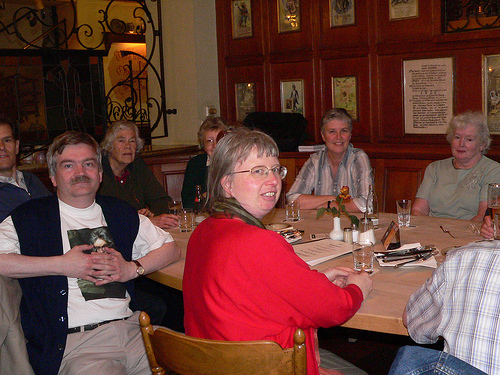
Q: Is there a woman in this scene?
A: Yes, there is a woman.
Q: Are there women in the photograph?
A: Yes, there is a woman.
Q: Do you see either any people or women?
A: Yes, there is a woman.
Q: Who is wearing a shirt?
A: The woman is wearing a shirt.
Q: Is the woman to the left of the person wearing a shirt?
A: Yes, the woman is wearing a shirt.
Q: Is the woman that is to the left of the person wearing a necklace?
A: No, the woman is wearing a shirt.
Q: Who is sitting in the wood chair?
A: The woman is sitting in the chair.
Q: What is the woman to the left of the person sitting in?
A: The woman is sitting in the chair.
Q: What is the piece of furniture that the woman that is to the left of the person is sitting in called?
A: The piece of furniture is a chair.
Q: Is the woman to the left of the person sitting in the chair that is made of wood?
A: Yes, the woman is sitting in the chair.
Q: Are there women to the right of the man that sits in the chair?
A: Yes, there is a woman to the right of the man.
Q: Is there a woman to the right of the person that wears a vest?
A: Yes, there is a woman to the right of the man.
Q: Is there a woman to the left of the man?
A: No, the woman is to the right of the man.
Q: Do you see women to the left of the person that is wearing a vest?
A: No, the woman is to the right of the man.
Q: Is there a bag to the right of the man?
A: No, there is a woman to the right of the man.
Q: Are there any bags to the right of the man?
A: No, there is a woman to the right of the man.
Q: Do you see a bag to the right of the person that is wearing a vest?
A: No, there is a woman to the right of the man.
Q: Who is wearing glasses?
A: The woman is wearing glasses.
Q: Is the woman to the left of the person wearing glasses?
A: Yes, the woman is wearing glasses.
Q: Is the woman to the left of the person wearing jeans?
A: No, the woman is wearing glasses.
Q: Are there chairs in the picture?
A: Yes, there is a chair.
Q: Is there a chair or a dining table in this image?
A: Yes, there is a chair.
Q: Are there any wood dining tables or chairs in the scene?
A: Yes, there is a wood chair.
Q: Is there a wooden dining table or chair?
A: Yes, there is a wood chair.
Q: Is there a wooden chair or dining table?
A: Yes, there is a wood chair.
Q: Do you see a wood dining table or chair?
A: Yes, there is a wood chair.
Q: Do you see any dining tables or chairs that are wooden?
A: Yes, the chair is wooden.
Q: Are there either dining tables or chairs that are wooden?
A: Yes, the chair is wooden.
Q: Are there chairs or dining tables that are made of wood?
A: Yes, the chair is made of wood.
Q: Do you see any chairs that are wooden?
A: Yes, there is a wood chair.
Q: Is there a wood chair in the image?
A: Yes, there is a wood chair.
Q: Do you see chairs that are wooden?
A: Yes, there is a chair that is wooden.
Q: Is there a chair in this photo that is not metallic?
A: Yes, there is a wooden chair.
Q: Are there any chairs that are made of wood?
A: Yes, there is a chair that is made of wood.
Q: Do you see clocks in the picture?
A: No, there are no clocks.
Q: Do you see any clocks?
A: No, there are no clocks.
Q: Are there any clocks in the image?
A: No, there are no clocks.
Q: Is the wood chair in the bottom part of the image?
A: Yes, the chair is in the bottom of the image.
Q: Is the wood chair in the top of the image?
A: No, the chair is in the bottom of the image.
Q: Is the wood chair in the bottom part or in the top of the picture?
A: The chair is in the bottom of the image.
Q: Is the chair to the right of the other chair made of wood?
A: Yes, the chair is made of wood.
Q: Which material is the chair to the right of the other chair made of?
A: The chair is made of wood.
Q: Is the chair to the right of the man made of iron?
A: No, the chair is made of wood.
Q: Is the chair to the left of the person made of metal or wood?
A: The chair is made of wood.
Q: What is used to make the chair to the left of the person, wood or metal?
A: The chair is made of wood.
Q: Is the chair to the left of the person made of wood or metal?
A: The chair is made of wood.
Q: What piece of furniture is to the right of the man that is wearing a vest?
A: The piece of furniture is a chair.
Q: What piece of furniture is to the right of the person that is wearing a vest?
A: The piece of furniture is a chair.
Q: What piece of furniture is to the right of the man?
A: The piece of furniture is a chair.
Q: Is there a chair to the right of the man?
A: Yes, there is a chair to the right of the man.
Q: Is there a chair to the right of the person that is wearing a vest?
A: Yes, there is a chair to the right of the man.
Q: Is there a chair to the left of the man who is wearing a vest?
A: No, the chair is to the right of the man.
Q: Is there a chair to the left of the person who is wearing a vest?
A: No, the chair is to the right of the man.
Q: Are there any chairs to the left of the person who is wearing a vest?
A: No, the chair is to the right of the man.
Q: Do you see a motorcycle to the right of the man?
A: No, there is a chair to the right of the man.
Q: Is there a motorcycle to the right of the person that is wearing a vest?
A: No, there is a chair to the right of the man.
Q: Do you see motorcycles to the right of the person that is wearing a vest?
A: No, there is a chair to the right of the man.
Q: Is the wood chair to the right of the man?
A: Yes, the chair is to the right of the man.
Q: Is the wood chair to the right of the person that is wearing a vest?
A: Yes, the chair is to the right of the man.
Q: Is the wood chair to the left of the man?
A: No, the chair is to the right of the man.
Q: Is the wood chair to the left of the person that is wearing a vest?
A: No, the chair is to the right of the man.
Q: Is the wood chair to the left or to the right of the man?
A: The chair is to the right of the man.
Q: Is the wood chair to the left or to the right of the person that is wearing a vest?
A: The chair is to the right of the man.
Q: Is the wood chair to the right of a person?
A: No, the chair is to the left of a person.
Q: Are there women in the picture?
A: Yes, there is a woman.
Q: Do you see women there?
A: Yes, there is a woman.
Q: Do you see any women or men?
A: Yes, there is a woman.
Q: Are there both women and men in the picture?
A: Yes, there are both a woman and a man.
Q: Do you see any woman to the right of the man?
A: Yes, there is a woman to the right of the man.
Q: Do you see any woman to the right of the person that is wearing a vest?
A: Yes, there is a woman to the right of the man.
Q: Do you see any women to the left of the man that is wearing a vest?
A: No, the woman is to the right of the man.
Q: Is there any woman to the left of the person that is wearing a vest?
A: No, the woman is to the right of the man.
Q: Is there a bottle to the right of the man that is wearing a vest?
A: No, there is a woman to the right of the man.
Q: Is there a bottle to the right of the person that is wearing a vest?
A: No, there is a woman to the right of the man.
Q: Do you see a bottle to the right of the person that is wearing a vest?
A: No, there is a woman to the right of the man.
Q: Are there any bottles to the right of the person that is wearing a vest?
A: No, there is a woman to the right of the man.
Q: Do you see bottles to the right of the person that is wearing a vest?
A: No, there is a woman to the right of the man.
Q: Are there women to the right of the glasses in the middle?
A: Yes, there is a woman to the right of the glasses.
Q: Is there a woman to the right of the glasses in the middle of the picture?
A: Yes, there is a woman to the right of the glasses.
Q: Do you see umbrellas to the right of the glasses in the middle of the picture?
A: No, there is a woman to the right of the glasses.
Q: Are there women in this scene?
A: Yes, there is a woman.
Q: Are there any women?
A: Yes, there is a woman.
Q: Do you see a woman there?
A: Yes, there is a woman.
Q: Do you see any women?
A: Yes, there is a woman.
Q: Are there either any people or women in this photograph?
A: Yes, there is a woman.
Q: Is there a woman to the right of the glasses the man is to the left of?
A: Yes, there is a woman to the right of the glasses.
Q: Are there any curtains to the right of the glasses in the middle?
A: No, there is a woman to the right of the glasses.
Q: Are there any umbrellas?
A: No, there are no umbrellas.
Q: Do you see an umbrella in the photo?
A: No, there are no umbrellas.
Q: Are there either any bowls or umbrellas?
A: No, there are no umbrellas or bowls.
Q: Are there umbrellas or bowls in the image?
A: No, there are no umbrellas or bowls.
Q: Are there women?
A: Yes, there is a woman.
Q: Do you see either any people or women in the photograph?
A: Yes, there is a woman.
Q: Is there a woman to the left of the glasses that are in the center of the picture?
A: Yes, there is a woman to the left of the glasses.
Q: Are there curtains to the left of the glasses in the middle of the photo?
A: No, there is a woman to the left of the glasses.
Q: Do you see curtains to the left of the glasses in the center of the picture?
A: No, there is a woman to the left of the glasses.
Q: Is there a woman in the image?
A: Yes, there is a woman.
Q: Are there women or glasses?
A: Yes, there is a woman.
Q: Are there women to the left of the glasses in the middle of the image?
A: Yes, there is a woman to the left of the glasses.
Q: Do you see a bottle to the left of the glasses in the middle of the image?
A: No, there is a woman to the left of the glasses.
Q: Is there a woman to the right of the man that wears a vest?
A: Yes, there is a woman to the right of the man.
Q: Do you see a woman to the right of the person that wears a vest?
A: Yes, there is a woman to the right of the man.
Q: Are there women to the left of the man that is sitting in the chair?
A: No, the woman is to the right of the man.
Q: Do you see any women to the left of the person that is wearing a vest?
A: No, the woman is to the right of the man.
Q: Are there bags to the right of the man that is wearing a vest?
A: No, there is a woman to the right of the man.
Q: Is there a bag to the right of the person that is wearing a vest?
A: No, there is a woman to the right of the man.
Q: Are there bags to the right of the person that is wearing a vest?
A: No, there is a woman to the right of the man.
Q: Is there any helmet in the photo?
A: No, there are no helmets.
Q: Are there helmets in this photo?
A: No, there are no helmets.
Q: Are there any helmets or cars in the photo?
A: No, there are no helmets or cars.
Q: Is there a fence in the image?
A: No, there are no fences.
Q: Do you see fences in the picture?
A: No, there are no fences.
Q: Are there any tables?
A: Yes, there is a table.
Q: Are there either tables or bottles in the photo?
A: Yes, there is a table.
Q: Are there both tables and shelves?
A: No, there is a table but no shelves.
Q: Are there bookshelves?
A: No, there are no bookshelves.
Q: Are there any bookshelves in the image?
A: No, there are no bookshelves.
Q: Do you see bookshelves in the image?
A: No, there are no bookshelves.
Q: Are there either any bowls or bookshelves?
A: No, there are no bookshelves or bowls.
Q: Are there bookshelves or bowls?
A: No, there are no bookshelves or bowls.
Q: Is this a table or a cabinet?
A: This is a table.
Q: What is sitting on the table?
A: The salt is sitting on the table.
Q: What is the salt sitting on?
A: The salt is sitting on the table.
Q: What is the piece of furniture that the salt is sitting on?
A: The piece of furniture is a table.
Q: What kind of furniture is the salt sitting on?
A: The salt is sitting on the table.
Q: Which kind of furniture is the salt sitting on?
A: The salt is sitting on the table.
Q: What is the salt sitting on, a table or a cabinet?
A: The salt is sitting on a table.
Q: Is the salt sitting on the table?
A: Yes, the salt is sitting on the table.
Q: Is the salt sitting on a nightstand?
A: No, the salt is sitting on the table.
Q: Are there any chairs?
A: Yes, there is a chair.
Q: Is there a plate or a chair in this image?
A: Yes, there is a chair.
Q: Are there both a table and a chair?
A: Yes, there are both a chair and a table.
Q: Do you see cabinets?
A: No, there are no cabinets.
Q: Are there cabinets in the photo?
A: No, there are no cabinets.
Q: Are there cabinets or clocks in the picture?
A: No, there are no cabinets or clocks.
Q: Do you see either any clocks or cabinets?
A: No, there are no cabinets or clocks.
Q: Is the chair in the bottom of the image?
A: Yes, the chair is in the bottom of the image.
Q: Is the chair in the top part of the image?
A: No, the chair is in the bottom of the image.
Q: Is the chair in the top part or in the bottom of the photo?
A: The chair is in the bottom of the image.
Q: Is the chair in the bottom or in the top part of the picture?
A: The chair is in the bottom of the image.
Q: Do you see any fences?
A: No, there are no fences.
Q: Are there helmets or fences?
A: No, there are no fences or helmets.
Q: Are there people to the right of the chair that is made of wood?
A: Yes, there is a person to the right of the chair.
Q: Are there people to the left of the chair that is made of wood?
A: No, the person is to the right of the chair.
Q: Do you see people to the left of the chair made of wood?
A: No, the person is to the right of the chair.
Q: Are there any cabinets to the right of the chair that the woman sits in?
A: No, there is a person to the right of the chair.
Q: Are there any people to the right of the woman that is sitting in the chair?
A: Yes, there is a person to the right of the woman.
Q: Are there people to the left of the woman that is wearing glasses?
A: No, the person is to the right of the woman.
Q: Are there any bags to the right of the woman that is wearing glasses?
A: No, there is a person to the right of the woman.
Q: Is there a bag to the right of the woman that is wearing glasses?
A: No, there is a person to the right of the woman.